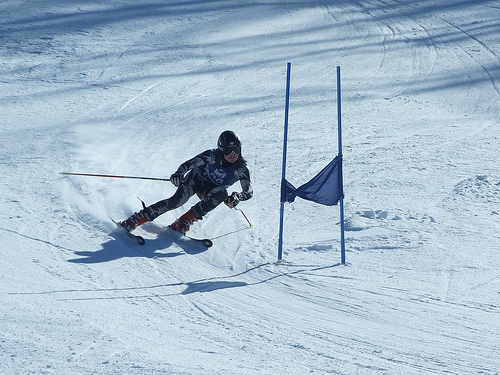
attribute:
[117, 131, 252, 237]
person — skiing, skiig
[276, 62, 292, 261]
slalom pole — blue, checkpoint area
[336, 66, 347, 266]
slalom pole — blue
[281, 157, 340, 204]
flag — blue, marker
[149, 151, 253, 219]
suit — blue, white, snow suit, black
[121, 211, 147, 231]
boot — red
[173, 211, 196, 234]
boot — red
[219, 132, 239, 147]
helmet — black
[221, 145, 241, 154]
goggles — snow goggles, dark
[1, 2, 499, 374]
snow — smooth, white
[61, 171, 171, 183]
ski pole — red, white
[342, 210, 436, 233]
snow pile — small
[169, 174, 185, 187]
glove — black, white